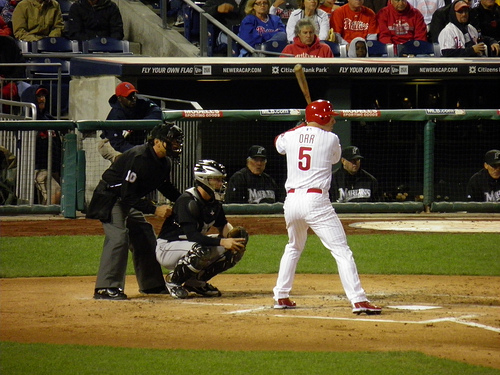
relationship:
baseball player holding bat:
[271, 98, 387, 332] [291, 61, 313, 100]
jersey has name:
[281, 125, 342, 195] [298, 132, 319, 144]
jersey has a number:
[281, 125, 342, 195] [297, 146, 314, 177]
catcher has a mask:
[160, 159, 251, 304] [204, 173, 235, 199]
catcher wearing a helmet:
[160, 159, 251, 304] [193, 157, 229, 186]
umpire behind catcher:
[90, 115, 177, 308] [160, 159, 251, 304]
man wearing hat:
[96, 79, 164, 166] [113, 77, 139, 101]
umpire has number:
[90, 115, 177, 308] [124, 168, 141, 187]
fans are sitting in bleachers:
[208, 1, 498, 54] [2, 0, 499, 74]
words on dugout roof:
[135, 65, 220, 78] [70, 51, 498, 80]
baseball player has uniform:
[271, 98, 387, 332] [277, 126, 363, 302]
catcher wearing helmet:
[160, 159, 251, 304] [193, 157, 229, 186]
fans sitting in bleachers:
[208, 1, 498, 54] [2, 0, 499, 74]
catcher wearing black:
[160, 159, 251, 304] [166, 194, 204, 236]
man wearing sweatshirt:
[96, 79, 164, 166] [107, 103, 155, 143]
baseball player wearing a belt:
[271, 98, 387, 332] [283, 186, 335, 194]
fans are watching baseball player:
[208, 1, 498, 54] [271, 98, 387, 332]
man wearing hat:
[101, 79, 155, 166] [113, 77, 139, 101]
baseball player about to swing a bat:
[271, 98, 387, 332] [291, 61, 313, 100]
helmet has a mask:
[193, 157, 229, 186] [204, 173, 235, 199]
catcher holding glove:
[160, 159, 251, 304] [225, 226, 249, 258]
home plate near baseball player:
[384, 301, 446, 314] [271, 98, 387, 332]